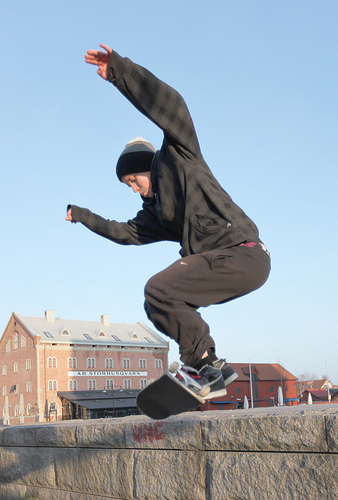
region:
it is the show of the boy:
[177, 358, 225, 399]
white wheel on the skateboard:
[169, 358, 180, 372]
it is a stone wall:
[0, 412, 335, 497]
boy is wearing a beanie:
[110, 136, 156, 171]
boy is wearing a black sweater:
[78, 123, 294, 253]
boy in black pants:
[134, 249, 283, 372]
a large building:
[0, 305, 166, 419]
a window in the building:
[45, 353, 61, 368]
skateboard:
[139, 365, 216, 421]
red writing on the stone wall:
[120, 420, 183, 455]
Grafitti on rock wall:
[126, 419, 171, 444]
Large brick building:
[0, 310, 170, 421]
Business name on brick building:
[63, 369, 147, 379]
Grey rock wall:
[3, 401, 334, 492]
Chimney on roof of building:
[40, 308, 60, 323]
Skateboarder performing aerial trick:
[57, 39, 275, 423]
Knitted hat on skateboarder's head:
[115, 137, 158, 179]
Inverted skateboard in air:
[127, 363, 211, 422]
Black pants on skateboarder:
[140, 245, 274, 361]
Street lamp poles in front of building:
[100, 383, 127, 417]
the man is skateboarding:
[51, 130, 259, 451]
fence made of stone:
[20, 411, 249, 497]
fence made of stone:
[145, 404, 297, 486]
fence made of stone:
[124, 374, 261, 497]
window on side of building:
[47, 357, 63, 369]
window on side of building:
[63, 357, 78, 371]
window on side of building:
[83, 356, 95, 368]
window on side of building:
[104, 356, 116, 367]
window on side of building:
[120, 356, 130, 369]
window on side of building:
[137, 358, 150, 371]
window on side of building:
[47, 380, 58, 390]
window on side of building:
[66, 378, 80, 390]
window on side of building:
[79, 375, 100, 389]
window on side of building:
[102, 377, 115, 386]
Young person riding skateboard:
[65, 42, 271, 420]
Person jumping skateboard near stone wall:
[64, 42, 270, 420]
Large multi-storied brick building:
[0, 309, 170, 423]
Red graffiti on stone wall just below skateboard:
[131, 421, 166, 442]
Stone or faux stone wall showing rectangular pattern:
[1, 401, 337, 497]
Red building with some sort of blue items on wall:
[200, 362, 299, 408]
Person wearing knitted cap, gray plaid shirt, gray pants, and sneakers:
[65, 43, 270, 399]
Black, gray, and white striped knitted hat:
[115, 135, 157, 182]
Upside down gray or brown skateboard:
[135, 361, 210, 420]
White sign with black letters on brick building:
[66, 370, 147, 376]